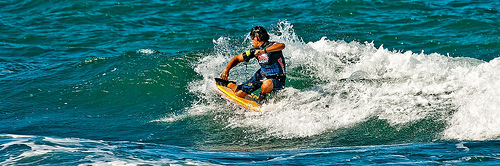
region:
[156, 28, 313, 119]
man wake boaring in ocean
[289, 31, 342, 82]
white and green waves in ocean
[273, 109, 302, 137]
white and green waves in ocean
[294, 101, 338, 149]
white and green waves in ocean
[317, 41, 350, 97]
white and green waves in ocean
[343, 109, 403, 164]
white and green waves in ocean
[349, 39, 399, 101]
white and green waves in ocean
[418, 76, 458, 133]
white and green waves in ocean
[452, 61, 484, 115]
white and green waves in ocean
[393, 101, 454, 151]
white and green waves in ocean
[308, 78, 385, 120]
the water is white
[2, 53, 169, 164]
the water is blue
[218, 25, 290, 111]
man is surfing in the water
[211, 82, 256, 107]
surfboard is yellow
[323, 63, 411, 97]
shadow in the water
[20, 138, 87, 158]
bubbles in the water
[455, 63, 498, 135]
waves in the water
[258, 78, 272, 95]
the surfers knee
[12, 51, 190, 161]
the ocean water is blue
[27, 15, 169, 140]
The water looks green.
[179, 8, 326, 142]
The man is surfing.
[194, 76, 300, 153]
this is a surfboard.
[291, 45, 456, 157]
The waves are nice.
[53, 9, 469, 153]
The waters are pretty choppy.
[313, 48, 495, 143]
The waves are white at the breakers.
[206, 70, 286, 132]
The board is yellow.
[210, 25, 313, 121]
The man is very wet.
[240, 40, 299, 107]
The man's wetsuit is black.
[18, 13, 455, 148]
This is in the ocean.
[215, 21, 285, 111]
man on a surfboard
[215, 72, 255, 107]
yellow surfboard cutting through the waves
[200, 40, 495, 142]
The white cap of the wave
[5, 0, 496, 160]
blue-green ocean water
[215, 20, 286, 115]
man with dark hair riding a surfboard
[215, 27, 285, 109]
boarder on a yellow board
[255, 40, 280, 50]
rider's left arm up in the air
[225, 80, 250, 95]
Surfer's right knee touching the board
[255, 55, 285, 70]
advertisers printed on the surfer's wet suit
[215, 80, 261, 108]
yellow surfboard in the water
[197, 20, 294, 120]
person on a yellow surfboard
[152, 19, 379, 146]
person surfing in white breaking wave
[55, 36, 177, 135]
ocean is a deep and clear blue green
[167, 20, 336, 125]
person surfing in blue green ocean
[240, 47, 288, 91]
blue and lime green wetsuit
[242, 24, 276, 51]
person has short and dark wet hair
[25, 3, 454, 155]
ocean water is turbulent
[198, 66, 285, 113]
kneeling awkwardly on yellow board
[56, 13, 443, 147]
person riding waves on a bright sunny day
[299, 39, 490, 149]
white caps of an ocean wave